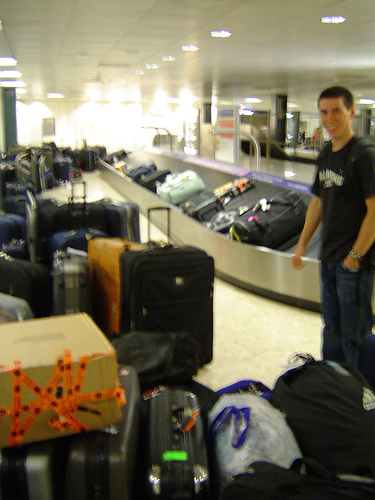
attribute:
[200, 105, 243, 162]
sign — white, orange, blue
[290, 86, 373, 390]
man — young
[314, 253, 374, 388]
jeans — dark blue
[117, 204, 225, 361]
black luggage — large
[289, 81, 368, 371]
young man — smiling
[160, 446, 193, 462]
tag — green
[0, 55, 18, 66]
light — bright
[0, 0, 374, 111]
ceiling — white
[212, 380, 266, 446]
bag — white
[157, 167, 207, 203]
luggage — green